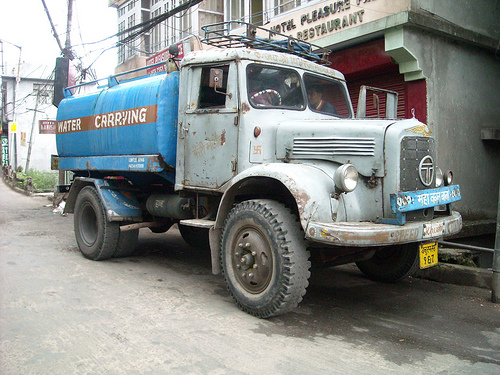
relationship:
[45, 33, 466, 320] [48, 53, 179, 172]
truck has tank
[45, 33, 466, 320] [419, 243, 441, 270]
truck has license plate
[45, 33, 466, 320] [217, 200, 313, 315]
truck has front tire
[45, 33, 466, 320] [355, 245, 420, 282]
truck has front tire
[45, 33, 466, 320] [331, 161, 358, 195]
truck has headlight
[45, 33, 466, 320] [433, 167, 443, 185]
truck has headlight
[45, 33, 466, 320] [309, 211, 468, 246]
truck has bumper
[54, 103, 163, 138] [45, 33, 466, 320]
sign on truck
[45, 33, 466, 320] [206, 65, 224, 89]
truck has side mirror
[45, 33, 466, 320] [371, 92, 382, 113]
truck has side mirror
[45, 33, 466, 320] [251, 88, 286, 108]
truck has steering wheel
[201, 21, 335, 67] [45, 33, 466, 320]
rack on top of truck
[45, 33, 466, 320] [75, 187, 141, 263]
truck has rear tire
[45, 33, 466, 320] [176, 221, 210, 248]
truck has rear tire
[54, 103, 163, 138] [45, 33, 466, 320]
sign on side of truck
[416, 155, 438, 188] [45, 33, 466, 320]
logo on truck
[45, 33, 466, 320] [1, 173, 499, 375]
truck on road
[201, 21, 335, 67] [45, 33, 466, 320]
rack on truck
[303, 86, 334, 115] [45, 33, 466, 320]
man inside truck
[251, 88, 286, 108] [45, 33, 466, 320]
steering wheel inside truck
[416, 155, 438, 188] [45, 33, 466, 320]
logo on front of truck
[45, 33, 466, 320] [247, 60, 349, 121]
truck has windshield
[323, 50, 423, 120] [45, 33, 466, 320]
garage behind truck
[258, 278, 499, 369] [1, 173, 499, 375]
stain on road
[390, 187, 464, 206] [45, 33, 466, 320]
sign on front of truck